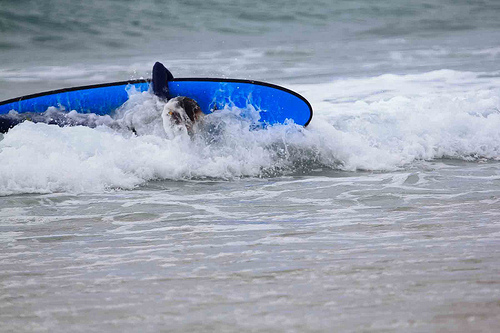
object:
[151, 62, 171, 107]
shirt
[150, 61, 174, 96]
person's arm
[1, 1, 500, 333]
waves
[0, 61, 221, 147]
person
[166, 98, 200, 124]
dark hair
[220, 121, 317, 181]
ocean wave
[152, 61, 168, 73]
elbow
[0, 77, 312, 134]
board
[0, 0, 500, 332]
ocean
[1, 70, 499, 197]
spray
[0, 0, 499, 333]
water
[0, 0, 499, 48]
clouds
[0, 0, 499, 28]
sky